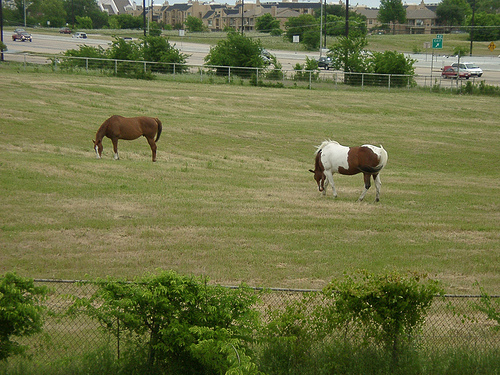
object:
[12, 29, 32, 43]
truck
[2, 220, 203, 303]
grass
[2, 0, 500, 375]
field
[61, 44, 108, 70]
tree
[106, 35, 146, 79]
tree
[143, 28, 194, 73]
tree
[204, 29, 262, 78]
tree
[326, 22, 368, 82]
tree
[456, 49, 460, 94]
pole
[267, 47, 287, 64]
road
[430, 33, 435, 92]
pole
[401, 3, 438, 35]
building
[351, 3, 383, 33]
building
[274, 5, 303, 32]
building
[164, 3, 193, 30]
building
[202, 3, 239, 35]
building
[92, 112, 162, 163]
horse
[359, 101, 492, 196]
grass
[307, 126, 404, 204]
horse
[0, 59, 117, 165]
grass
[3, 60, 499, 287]
pasture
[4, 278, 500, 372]
fence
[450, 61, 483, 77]
car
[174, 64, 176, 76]
pole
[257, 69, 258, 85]
pole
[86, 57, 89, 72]
pole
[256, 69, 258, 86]
pole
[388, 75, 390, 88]
pole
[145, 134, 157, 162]
leg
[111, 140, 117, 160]
leg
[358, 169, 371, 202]
leg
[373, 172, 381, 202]
leg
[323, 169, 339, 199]
leg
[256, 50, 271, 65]
car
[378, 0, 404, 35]
trees